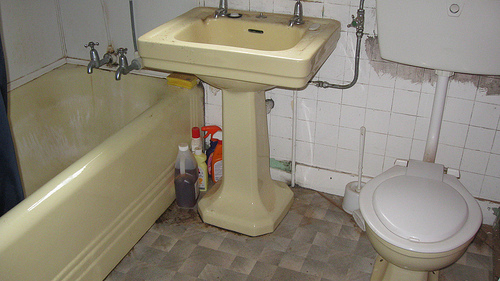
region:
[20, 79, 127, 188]
Dirty yellow bathtub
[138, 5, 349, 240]
Dirty yellow pedestal sink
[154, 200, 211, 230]
Dirty gray tile floor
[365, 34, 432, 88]
Dirty white wall tile behind the toilet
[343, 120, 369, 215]
White toilet bowl brush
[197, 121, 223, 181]
Orange bottle with a spray top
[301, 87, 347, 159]
White tile on the wall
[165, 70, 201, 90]
Yellow bar of soap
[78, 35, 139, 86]
Silver bathtub faucet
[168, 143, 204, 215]
Plastic bottle of dark liquid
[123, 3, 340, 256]
the sink is a yellowish color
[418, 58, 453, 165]
a long pipe on the toilet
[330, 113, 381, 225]
the toilet brush is in its holder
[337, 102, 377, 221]
the toilet brush is white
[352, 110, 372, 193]
this is a plastic toilet brush handle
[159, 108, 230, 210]
these are cleaning chemicals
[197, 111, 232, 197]
there are plastic spray bottles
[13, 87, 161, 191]
there are white water stains in the tub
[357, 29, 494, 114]
there is water damage on the tile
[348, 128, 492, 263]
a white plastic toilet seat cover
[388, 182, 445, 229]
the toilet lid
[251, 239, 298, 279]
the tile on the floor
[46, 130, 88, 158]
the tub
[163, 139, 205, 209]
a bottle on the floor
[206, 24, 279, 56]
the sink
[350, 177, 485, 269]
the toilet is white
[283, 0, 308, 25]
the faucet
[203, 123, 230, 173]
an orange bottle on the floor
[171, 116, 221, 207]
bottles on the floor under the sink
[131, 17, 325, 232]
cream colored pedestal sink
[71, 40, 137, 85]
water faucets over the tub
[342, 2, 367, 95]
silver pipe running along the wall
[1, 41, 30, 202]
curtain hanging in the shower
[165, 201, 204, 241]
floor is dirty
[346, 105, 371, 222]
toilet brush in holder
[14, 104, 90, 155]
stains in the tub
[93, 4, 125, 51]
stains on the wall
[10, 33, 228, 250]
tub next to the sink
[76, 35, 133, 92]
handles on the shower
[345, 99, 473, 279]
toilet next to the sink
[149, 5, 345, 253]
sink next to the tub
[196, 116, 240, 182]
the bottle is orange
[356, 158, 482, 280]
White toilet seat and base.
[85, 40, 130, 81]
Hot and cold faucets in a bathtub.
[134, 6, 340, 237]
Cream colored sink with two faucets.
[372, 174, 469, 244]
White toilet seat lid.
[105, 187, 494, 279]
A dirty grey tiled floor.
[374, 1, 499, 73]
A wide white toilet tank.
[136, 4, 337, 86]
the sink is beige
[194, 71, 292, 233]
the sink is beige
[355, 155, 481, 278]
the toilet is white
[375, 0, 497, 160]
the toilet is white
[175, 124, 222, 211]
bottles on the floor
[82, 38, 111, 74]
the faucet is silver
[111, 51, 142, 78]
the faucet is silver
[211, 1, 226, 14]
the faucet is silver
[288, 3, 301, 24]
the faucet is silver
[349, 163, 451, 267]
a toilet in the bathroom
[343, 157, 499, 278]
a toilet is white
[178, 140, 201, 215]
a bottle on the floor